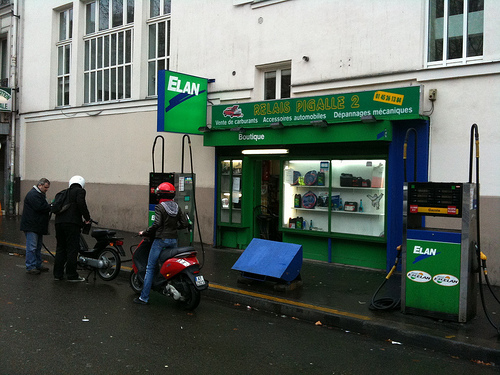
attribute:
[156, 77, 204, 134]
sign — french, elan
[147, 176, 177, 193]
helmet — red, white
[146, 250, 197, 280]
motorcycle — red, black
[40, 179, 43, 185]
hair — gray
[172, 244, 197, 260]
seat — black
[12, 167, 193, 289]
men — standing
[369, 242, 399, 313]
pump — green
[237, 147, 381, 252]
shop — green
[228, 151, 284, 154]
light — white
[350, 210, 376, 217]
shelves — white